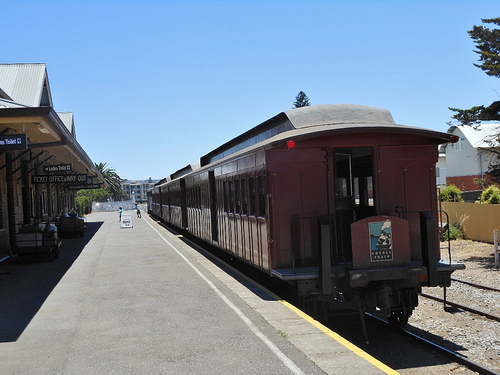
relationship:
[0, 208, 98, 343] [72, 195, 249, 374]
shadow on sidewalk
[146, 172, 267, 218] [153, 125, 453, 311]
windows on train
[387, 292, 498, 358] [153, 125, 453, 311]
tracks under train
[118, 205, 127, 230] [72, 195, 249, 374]
sign on sidewalk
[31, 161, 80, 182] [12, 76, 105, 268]
sign on building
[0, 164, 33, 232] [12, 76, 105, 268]
wall on building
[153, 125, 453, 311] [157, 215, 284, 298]
train casts shadow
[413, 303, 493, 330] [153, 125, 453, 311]
gravel under train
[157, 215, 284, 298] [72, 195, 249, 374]
shadow on sidewalk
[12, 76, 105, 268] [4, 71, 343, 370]
building on platform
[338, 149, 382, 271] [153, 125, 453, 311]
door on train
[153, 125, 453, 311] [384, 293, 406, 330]
train has wheel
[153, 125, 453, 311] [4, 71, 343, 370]
train near platform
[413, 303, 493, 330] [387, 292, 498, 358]
gravel near tracks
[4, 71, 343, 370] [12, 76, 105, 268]
platform outside building